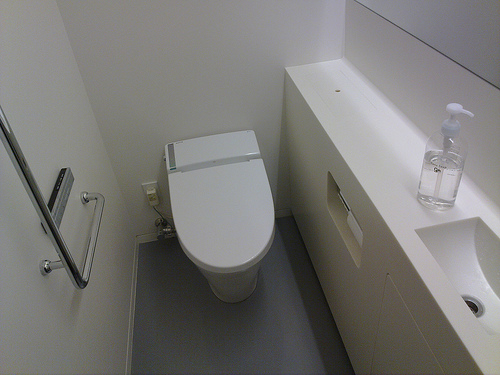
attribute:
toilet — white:
[166, 128, 275, 302]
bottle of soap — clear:
[415, 96, 471, 210]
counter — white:
[282, 60, 496, 374]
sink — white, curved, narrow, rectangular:
[414, 216, 500, 353]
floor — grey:
[125, 209, 352, 374]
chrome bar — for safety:
[1, 109, 101, 287]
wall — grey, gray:
[0, 1, 133, 374]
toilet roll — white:
[343, 209, 367, 247]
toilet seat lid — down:
[169, 166, 274, 269]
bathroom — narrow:
[2, 3, 495, 374]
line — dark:
[354, 1, 498, 99]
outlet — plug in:
[142, 179, 162, 203]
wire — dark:
[152, 203, 178, 235]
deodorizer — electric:
[42, 164, 71, 230]